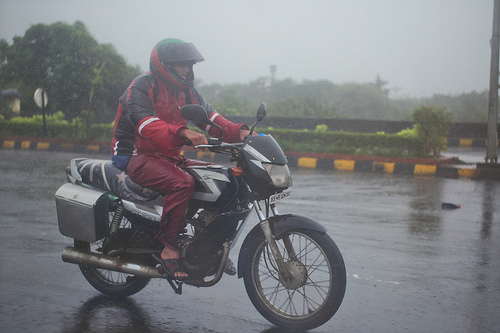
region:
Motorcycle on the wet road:
[24, 13, 369, 327]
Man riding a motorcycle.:
[61, 3, 256, 292]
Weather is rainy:
[5, 9, 495, 325]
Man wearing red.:
[103, 12, 248, 292]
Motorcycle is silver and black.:
[7, 121, 376, 325]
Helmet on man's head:
[135, 32, 217, 94]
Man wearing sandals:
[137, 242, 264, 294]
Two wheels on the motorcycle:
[45, 172, 379, 327]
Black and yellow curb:
[0, 128, 480, 184]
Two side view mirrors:
[165, 96, 296, 151]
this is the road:
[371, 207, 439, 297]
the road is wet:
[388, 233, 439, 317]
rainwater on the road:
[373, 180, 484, 214]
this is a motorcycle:
[58, 106, 344, 328]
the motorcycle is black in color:
[261, 134, 275, 156]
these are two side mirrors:
[180, 102, 275, 138]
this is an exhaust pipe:
[58, 242, 157, 285]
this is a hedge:
[295, 127, 421, 152]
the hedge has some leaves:
[303, 130, 380, 152]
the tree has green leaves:
[19, 37, 93, 128]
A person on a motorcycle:
[55, 25, 318, 330]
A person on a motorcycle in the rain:
[49, 25, 364, 321]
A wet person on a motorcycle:
[20, 25, 368, 321]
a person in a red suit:
[30, 35, 329, 282]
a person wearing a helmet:
[111, 25, 238, 182]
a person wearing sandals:
[96, 23, 240, 304]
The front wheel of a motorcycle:
[225, 174, 382, 331]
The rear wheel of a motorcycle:
[39, 214, 158, 303]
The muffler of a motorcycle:
[29, 183, 173, 306]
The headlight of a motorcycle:
[236, 152, 312, 202]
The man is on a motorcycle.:
[43, 23, 395, 331]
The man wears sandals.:
[151, 237, 203, 303]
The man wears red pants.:
[119, 150, 213, 256]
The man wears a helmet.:
[137, 29, 222, 94]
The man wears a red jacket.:
[97, 66, 265, 163]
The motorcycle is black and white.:
[52, 116, 399, 331]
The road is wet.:
[0, 148, 497, 330]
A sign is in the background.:
[20, 81, 57, 143]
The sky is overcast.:
[0, 1, 498, 106]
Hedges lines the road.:
[0, 90, 461, 160]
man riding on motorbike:
[36, 31, 365, 321]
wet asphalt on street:
[339, 203, 424, 250]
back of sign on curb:
[27, 76, 64, 137]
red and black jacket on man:
[115, 70, 217, 160]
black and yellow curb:
[322, 155, 411, 181]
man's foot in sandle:
[146, 241, 196, 291]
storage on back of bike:
[52, 173, 114, 250]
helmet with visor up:
[145, 31, 210, 96]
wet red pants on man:
[125, 136, 205, 246]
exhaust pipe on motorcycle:
[46, 237, 183, 283]